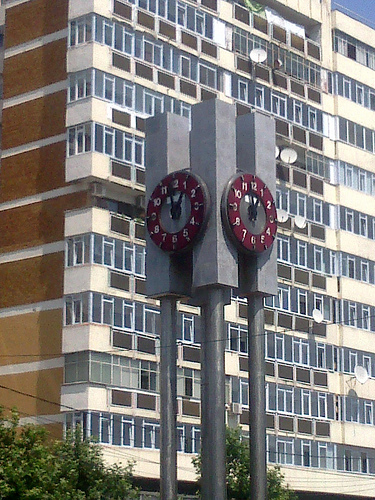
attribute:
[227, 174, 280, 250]
clock — large, round, purple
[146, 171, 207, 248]
clock — purple, round, large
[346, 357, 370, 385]
dish — large, white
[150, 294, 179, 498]
pole — thick, black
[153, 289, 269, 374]
poles — metal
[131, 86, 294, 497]
tower — clock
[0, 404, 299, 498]
trees — tall, green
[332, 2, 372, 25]
sky — blue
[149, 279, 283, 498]
iron columns — tall, gray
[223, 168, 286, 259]
clock — red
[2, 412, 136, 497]
trees — green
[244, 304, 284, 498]
pole — gray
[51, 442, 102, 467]
leaves — green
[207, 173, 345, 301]
clock — 12:59pm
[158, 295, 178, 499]
pole — gray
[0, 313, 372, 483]
electrical lines — black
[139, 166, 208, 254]
clock — red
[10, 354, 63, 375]
stripe — white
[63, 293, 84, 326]
window — open